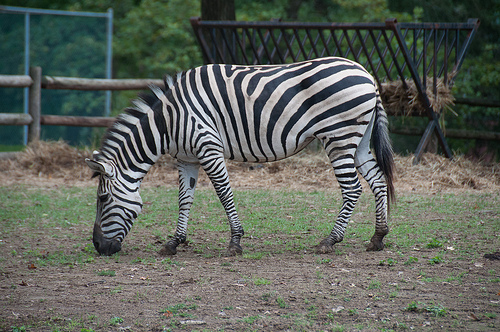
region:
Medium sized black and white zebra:
[37, 36, 425, 283]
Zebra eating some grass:
[61, 43, 410, 277]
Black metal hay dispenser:
[162, 6, 484, 175]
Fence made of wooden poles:
[0, 62, 181, 143]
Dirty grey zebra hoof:
[217, 231, 251, 266]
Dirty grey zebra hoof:
[307, 226, 350, 261]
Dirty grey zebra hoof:
[364, 223, 393, 265]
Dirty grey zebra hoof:
[153, 234, 193, 259]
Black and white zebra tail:
[367, 83, 422, 221]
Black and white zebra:
[30, 38, 433, 300]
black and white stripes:
[247, 72, 299, 119]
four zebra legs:
[157, 162, 401, 272]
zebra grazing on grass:
[80, 154, 167, 289]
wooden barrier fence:
[14, 58, 121, 154]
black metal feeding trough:
[179, 7, 477, 69]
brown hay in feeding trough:
[374, 53, 457, 138]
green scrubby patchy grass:
[14, 192, 64, 314]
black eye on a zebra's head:
[97, 190, 110, 204]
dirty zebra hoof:
[154, 235, 184, 260]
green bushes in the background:
[117, 8, 176, 65]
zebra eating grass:
[55, 51, 399, 257]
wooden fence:
[0, 65, 96, 142]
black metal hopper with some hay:
[391, 10, 462, 117]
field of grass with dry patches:
[305, 263, 490, 323]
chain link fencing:
[18, 3, 115, 60]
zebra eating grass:
[68, 143, 148, 257]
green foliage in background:
[128, 9, 184, 57]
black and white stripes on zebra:
[211, 77, 313, 122]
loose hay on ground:
[408, 164, 460, 186]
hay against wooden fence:
[6, 109, 78, 170]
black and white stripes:
[225, 78, 275, 130]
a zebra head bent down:
[79, 129, 139, 278]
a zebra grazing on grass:
[73, 208, 135, 278]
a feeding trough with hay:
[187, 8, 470, 192]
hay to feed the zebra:
[414, 78, 454, 110]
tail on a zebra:
[364, 86, 409, 231]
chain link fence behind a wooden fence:
[8, 3, 121, 70]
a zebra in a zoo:
[43, 22, 447, 308]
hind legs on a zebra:
[315, 140, 414, 292]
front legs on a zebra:
[147, 126, 261, 275]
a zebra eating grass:
[69, 59, 406, 266]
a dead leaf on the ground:
[334, 298, 351, 309]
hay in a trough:
[404, 83, 448, 104]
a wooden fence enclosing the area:
[16, 63, 117, 126]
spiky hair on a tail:
[379, 126, 395, 189]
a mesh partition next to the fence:
[14, 4, 103, 59]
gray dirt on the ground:
[284, 264, 314, 289]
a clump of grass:
[418, 229, 445, 253]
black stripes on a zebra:
[258, 86, 300, 123]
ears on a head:
[83, 159, 128, 182]